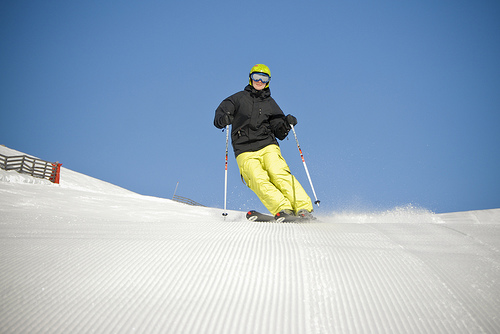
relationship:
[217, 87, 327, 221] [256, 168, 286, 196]
man wearing pants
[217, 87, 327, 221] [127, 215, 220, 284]
man in snow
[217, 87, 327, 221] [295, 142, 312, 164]
man has pole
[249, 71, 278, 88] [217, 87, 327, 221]
goggles on man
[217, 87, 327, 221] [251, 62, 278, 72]
man wearing helmet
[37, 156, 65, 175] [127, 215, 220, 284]
fence in snow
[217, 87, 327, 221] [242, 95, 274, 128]
man wearing jacket